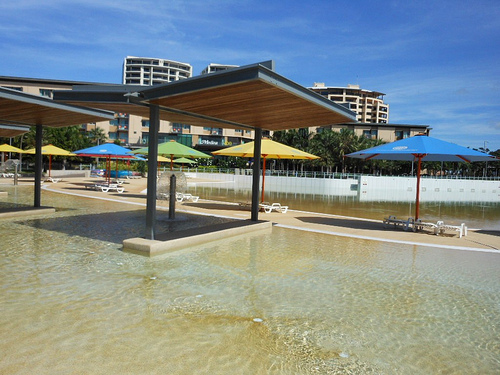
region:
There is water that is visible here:
[367, 265, 393, 352]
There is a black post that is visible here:
[138, 155, 191, 261]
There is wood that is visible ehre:
[248, 93, 274, 122]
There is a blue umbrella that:
[396, 130, 428, 190]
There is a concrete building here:
[138, 55, 148, 83]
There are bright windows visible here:
[126, 68, 133, 85]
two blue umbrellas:
[78, 133, 485, 230]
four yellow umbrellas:
[4, 133, 305, 190]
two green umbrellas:
[135, 134, 209, 201]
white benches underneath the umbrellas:
[91, 169, 473, 241]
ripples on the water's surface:
[9, 182, 491, 372]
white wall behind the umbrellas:
[187, 160, 497, 212]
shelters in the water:
[0, 73, 347, 253]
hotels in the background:
[117, 47, 387, 124]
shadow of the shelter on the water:
[26, 210, 219, 243]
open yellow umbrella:
[208, 112, 325, 225]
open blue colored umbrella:
[347, 124, 494, 244]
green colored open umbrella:
[135, 116, 210, 214]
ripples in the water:
[242, 260, 359, 350]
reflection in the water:
[292, 172, 369, 223]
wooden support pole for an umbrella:
[399, 146, 426, 231]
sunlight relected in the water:
[206, 296, 326, 345]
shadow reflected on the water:
[28, 203, 100, 255]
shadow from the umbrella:
[296, 200, 393, 244]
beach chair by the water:
[243, 191, 296, 224]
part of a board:
[477, 218, 493, 238]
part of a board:
[252, 89, 265, 100]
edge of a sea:
[367, 233, 377, 262]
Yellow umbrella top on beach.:
[215, 135, 322, 159]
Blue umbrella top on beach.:
[342, 133, 498, 168]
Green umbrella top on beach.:
[132, 139, 208, 156]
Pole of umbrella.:
[412, 153, 422, 219]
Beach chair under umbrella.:
[380, 213, 467, 238]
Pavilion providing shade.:
[52, 63, 360, 246]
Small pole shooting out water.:
[167, 173, 177, 216]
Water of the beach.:
[140, 170, 498, 230]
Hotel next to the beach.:
[0, 75, 265, 165]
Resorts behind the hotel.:
[122, 53, 392, 148]